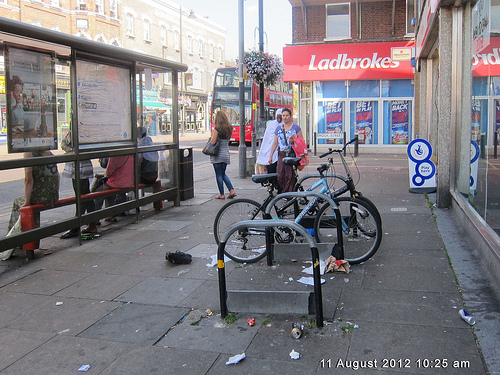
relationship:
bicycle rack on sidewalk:
[210, 138, 369, 283] [2, 147, 496, 369]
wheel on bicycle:
[212, 197, 264, 264] [213, 158, 381, 265]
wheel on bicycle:
[312, 197, 382, 264] [213, 158, 381, 265]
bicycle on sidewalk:
[183, 160, 420, 298] [2, 147, 496, 369]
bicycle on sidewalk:
[275, 128, 365, 198] [2, 147, 496, 369]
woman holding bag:
[202, 112, 237, 200] [201, 133, 219, 158]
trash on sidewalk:
[136, 237, 381, 374] [2, 147, 496, 369]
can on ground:
[457, 304, 478, 325] [5, 184, 498, 372]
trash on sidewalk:
[168, 244, 200, 268] [1, 132, 468, 374]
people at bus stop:
[268, 106, 298, 180] [0, 17, 188, 254]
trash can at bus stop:
[169, 142, 194, 200] [0, 17, 188, 254]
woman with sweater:
[271, 109, 311, 194] [289, 132, 311, 167]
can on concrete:
[288, 323, 304, 338] [1, 131, 498, 373]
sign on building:
[404, 133, 446, 205] [401, 1, 498, 298]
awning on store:
[282, 39, 422, 92] [283, 0, 433, 160]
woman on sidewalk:
[202, 108, 237, 199] [153, 189, 289, 339]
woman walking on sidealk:
[202, 108, 237, 199] [109, 217, 264, 348]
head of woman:
[282, 107, 293, 124] [271, 109, 311, 194]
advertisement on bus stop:
[4, 42, 58, 151] [0, 17, 188, 254]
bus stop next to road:
[0, 17, 188, 254] [0, 134, 238, 237]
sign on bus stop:
[4, 42, 58, 153] [7, 18, 196, 247]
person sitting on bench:
[8, 148, 58, 257] [13, 179, 161, 259]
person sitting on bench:
[89, 151, 135, 231] [13, 179, 161, 259]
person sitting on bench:
[133, 124, 157, 202] [13, 179, 161, 259]